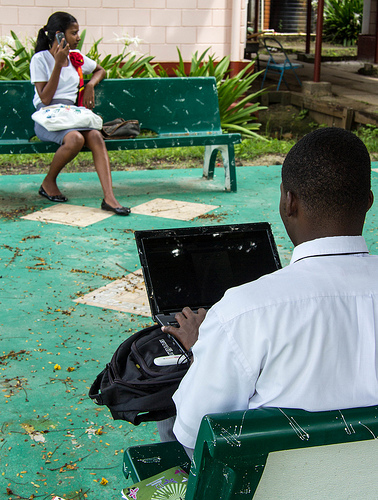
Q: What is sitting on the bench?
A: A woman on the phone.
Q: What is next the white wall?
A: A bench with woman on it.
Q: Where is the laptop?
A: On the man's lap.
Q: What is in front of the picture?
A: Back of man's head.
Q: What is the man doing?
A: He is using the black laptop.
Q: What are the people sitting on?
A: Benches.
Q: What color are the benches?
A: Green.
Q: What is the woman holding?
A: A phone.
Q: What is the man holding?
A: A laptop.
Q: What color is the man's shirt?
A: White.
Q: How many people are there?
A: Two.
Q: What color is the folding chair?
A: Blue.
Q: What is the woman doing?
A: Talking on her phone.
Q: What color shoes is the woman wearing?
A: Black.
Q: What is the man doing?
A: Typing on his laptop.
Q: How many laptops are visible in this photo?
A: One.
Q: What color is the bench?
A: Green.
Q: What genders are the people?
A: Male and female.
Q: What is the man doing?
A: Using laptop.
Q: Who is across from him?
A: A woman.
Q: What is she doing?
A: Talkingon phone.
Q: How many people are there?
A: Two.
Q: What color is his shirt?
A: White.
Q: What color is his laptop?
A: Black.